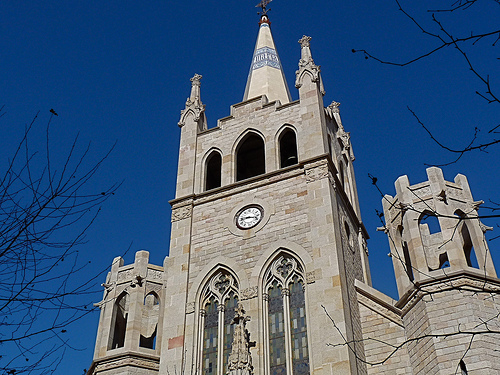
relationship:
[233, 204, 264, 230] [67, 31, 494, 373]
clock on front of building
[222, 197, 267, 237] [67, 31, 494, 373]
clock on outside of building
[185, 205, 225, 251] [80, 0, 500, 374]
wall on side of stone church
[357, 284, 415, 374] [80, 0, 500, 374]
wall on side of stone church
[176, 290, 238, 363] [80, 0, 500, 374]
wall on side of stone church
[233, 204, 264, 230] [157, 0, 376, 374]
clock on tower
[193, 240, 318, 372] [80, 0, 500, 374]
windows on stone church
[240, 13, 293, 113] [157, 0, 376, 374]
spire on tower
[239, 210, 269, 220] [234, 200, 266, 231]
number marks on clock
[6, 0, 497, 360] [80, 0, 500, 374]
blue sky behind stone church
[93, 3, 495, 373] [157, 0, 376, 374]
stone church with tower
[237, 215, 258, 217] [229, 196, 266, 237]
black hands on clock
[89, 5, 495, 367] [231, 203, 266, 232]
tower has clock